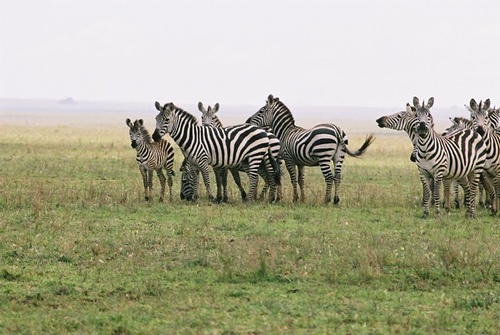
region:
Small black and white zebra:
[102, 106, 194, 216]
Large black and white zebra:
[233, 90, 383, 212]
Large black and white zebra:
[139, 93, 300, 211]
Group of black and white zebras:
[87, 61, 376, 228]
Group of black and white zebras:
[361, 64, 498, 245]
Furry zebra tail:
[335, 118, 382, 166]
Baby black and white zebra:
[115, 103, 186, 209]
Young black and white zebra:
[111, 96, 185, 218]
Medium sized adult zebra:
[150, 103, 287, 204]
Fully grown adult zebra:
[149, 81, 289, 214]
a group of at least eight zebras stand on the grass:
[116, 94, 498, 209]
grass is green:
[13, 198, 493, 328]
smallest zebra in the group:
[122, 113, 177, 200]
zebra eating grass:
[177, 157, 201, 205]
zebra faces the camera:
[408, 93, 483, 216]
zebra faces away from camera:
[248, 95, 375, 206]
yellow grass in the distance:
[0, 115, 122, 147]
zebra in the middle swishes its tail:
[243, 88, 373, 205]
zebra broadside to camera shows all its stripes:
[151, 102, 281, 203]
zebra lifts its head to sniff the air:
[371, 100, 413, 132]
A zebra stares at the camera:
[403, 98, 462, 200]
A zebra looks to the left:
[372, 103, 414, 129]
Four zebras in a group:
[114, 91, 371, 210]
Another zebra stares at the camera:
[467, 98, 498, 171]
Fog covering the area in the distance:
[2, 79, 125, 138]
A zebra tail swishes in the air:
[336, 125, 376, 161]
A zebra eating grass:
[177, 163, 204, 208]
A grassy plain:
[1, 230, 499, 332]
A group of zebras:
[124, 0, 499, 219]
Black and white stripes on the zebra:
[190, 125, 259, 157]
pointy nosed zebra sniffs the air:
[368, 107, 461, 210]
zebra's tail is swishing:
[331, 119, 379, 166]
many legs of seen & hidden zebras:
[418, 167, 499, 217]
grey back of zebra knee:
[332, 167, 344, 184]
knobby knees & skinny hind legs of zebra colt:
[156, 167, 175, 206]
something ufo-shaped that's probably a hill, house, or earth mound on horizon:
[53, 92, 82, 106]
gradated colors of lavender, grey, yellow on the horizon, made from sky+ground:
[0, 89, 499, 137]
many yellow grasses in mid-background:
[2, 114, 499, 170]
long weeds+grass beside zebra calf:
[1, 182, 144, 212]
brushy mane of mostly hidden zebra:
[437, 111, 477, 139]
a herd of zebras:
[117, 75, 497, 217]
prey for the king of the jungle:
[120, 77, 497, 226]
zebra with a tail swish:
[245, 91, 380, 204]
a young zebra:
[124, 108, 180, 208]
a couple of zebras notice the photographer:
[373, 75, 497, 221]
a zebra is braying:
[369, 101, 423, 141]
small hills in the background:
[13, 77, 127, 179]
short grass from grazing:
[40, 183, 497, 334]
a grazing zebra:
[172, 156, 209, 207]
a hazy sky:
[4, 0, 498, 142]